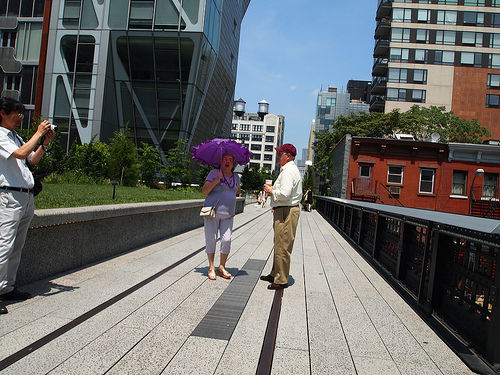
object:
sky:
[235, 0, 376, 168]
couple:
[191, 138, 302, 291]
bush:
[56, 131, 111, 176]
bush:
[241, 163, 266, 194]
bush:
[160, 139, 195, 188]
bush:
[133, 137, 166, 189]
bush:
[103, 122, 141, 187]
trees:
[310, 103, 493, 196]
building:
[327, 132, 500, 321]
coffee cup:
[265, 180, 272, 188]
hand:
[264, 184, 272, 194]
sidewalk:
[0, 193, 478, 374]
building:
[368, 0, 499, 144]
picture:
[0, 0, 500, 375]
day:
[0, 0, 500, 375]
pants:
[203, 213, 233, 254]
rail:
[312, 193, 500, 375]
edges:
[191, 138, 252, 169]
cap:
[274, 143, 297, 157]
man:
[0, 96, 57, 316]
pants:
[269, 207, 300, 286]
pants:
[0, 189, 36, 295]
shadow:
[0, 281, 80, 314]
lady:
[200, 152, 240, 280]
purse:
[200, 206, 216, 218]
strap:
[210, 173, 235, 210]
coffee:
[265, 179, 272, 186]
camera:
[40, 124, 61, 153]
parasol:
[190, 138, 253, 183]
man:
[264, 143, 303, 290]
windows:
[386, 0, 500, 108]